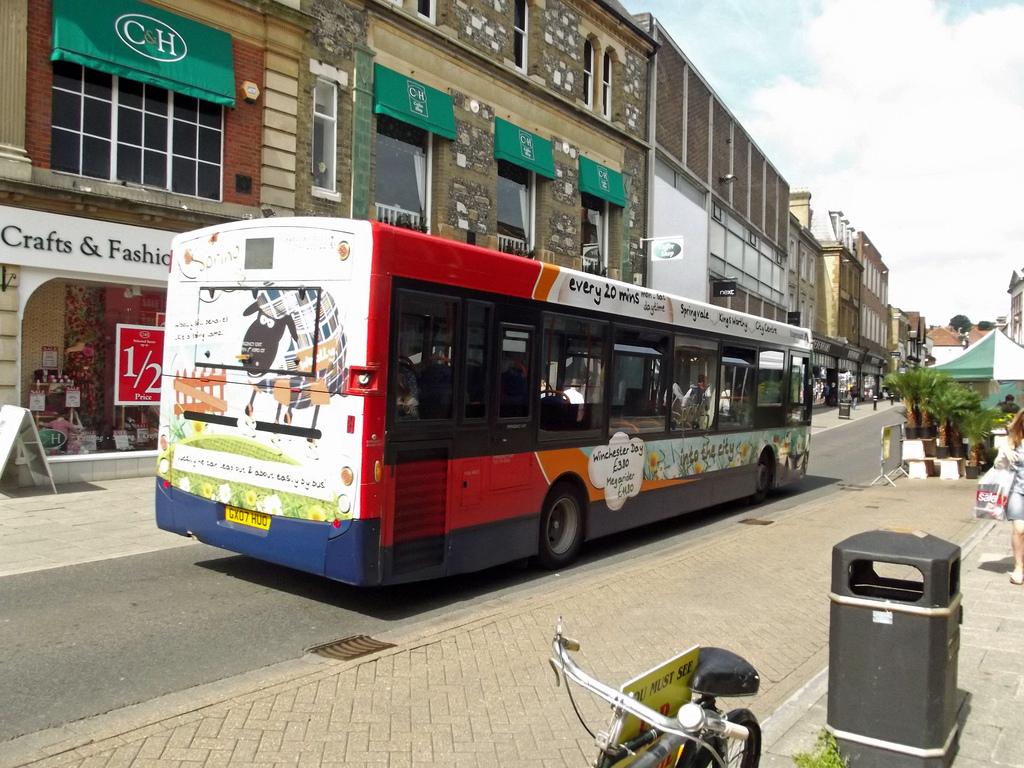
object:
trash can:
[788, 526, 982, 767]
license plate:
[217, 502, 272, 534]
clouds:
[886, 4, 1022, 261]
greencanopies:
[39, 8, 242, 120]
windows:
[782, 346, 814, 428]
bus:
[148, 210, 817, 596]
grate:
[314, 630, 394, 669]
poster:
[113, 322, 164, 409]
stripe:
[542, 304, 666, 438]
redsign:
[112, 324, 165, 405]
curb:
[0, 471, 882, 760]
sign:
[613, 640, 704, 748]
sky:
[790, 4, 1024, 186]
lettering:
[562, 267, 801, 347]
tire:
[536, 481, 588, 570]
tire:
[754, 453, 777, 502]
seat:
[684, 639, 758, 702]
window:
[54, 58, 117, 190]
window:
[109, 73, 177, 190]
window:
[164, 99, 232, 197]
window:
[377, 124, 434, 233]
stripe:
[142, 451, 810, 524]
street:
[2, 393, 1024, 768]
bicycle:
[546, 604, 772, 764]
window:
[491, 152, 536, 257]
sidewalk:
[0, 466, 1022, 758]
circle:
[673, 699, 713, 736]